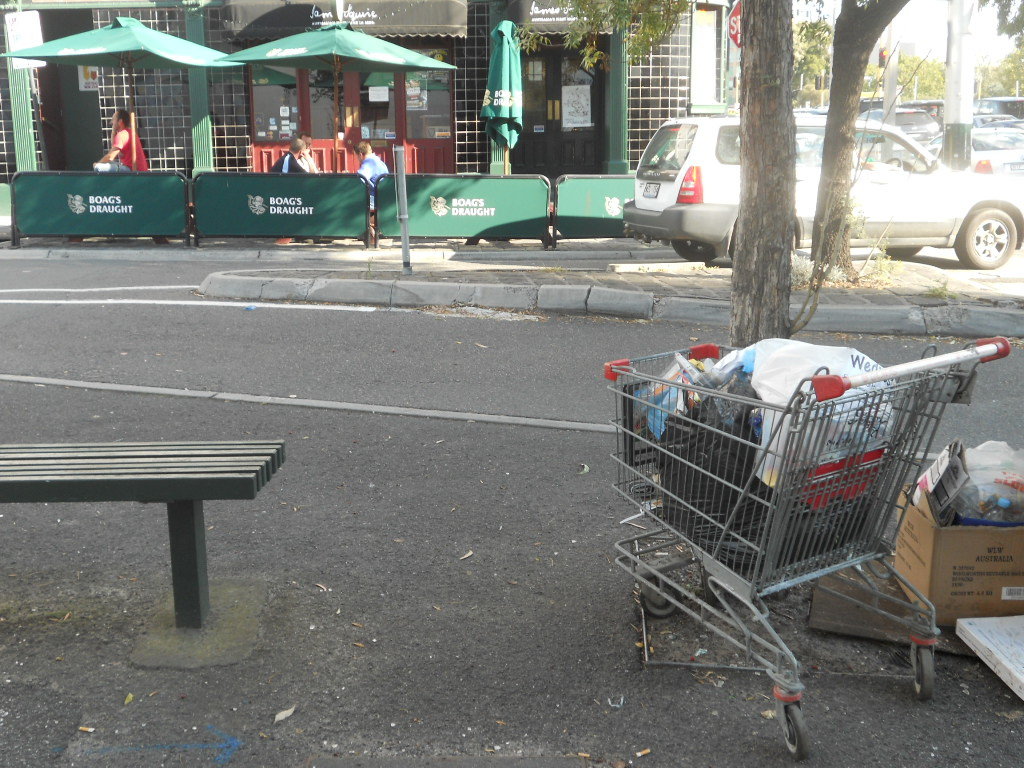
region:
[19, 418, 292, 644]
GREY PARK BENCH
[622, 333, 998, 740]
shopping cart being used for collection of miscellanous items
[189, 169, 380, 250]
beer advertisement on green fabric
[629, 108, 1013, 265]
white automobile with hatchback parked along street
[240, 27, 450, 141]
green umbrella used for shelter at an outdoor cafe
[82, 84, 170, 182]
man with red shirt sits outside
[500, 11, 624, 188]
wooden doors with brass guards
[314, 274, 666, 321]
concrete blocks provide barrier between street and walkway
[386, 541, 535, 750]
a view of road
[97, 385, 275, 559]
a view of bench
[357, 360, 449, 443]
a view of lines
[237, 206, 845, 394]
a view of curve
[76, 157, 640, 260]
green barrier near road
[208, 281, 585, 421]
road is dark grey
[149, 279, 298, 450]
white lines on road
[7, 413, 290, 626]
black bench on road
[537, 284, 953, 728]
grey shopping cart near tree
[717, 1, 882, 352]
grey trunk of tree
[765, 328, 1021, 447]
red and white cart handle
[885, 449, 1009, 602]
cardboard box near cart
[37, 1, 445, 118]
green canopies behind barrier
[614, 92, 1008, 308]
white van by barriers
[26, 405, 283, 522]
the seat of a bench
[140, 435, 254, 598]
the leg of a bench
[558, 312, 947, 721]
a full grocery cart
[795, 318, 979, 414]
the handle of a grocery cart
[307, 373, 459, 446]
a line on the road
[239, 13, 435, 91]
a big green umbrella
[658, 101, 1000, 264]
a car that is white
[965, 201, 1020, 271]
the wheel of a car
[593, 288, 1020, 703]
full shopping cart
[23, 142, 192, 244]
green and white barricade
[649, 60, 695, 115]
a window on the building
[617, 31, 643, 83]
a window on the building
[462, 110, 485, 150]
a window on the building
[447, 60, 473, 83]
a window on the building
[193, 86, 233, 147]
a window on the building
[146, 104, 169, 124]
a window on the building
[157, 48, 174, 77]
a window on the building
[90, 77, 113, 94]
a window on the building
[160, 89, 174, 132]
a window on the building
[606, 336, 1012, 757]
a silver and red shopping cart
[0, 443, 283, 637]
a wooden bench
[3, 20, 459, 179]
large, green umbrella shades